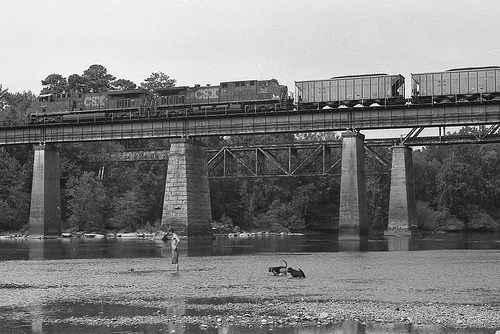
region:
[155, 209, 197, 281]
Boy standing by the river.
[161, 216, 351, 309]
A boy and his two dogs.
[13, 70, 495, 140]
Train on the tracks.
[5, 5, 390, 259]
Train crossing the river.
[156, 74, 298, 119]
CSX written on the train car.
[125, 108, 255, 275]
Pillar holding up the bridge.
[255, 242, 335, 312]
Two dogs resting for a minute.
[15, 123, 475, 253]
Four pillars are required to hold up the tracks.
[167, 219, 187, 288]
Young boy in just shorts.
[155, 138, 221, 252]
A stone pillar in the water.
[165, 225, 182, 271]
young man in water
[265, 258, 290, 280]
a dog in water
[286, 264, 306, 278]
a dog in water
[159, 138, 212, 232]
a large stone pillar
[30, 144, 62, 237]
a large stone pillar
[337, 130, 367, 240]
a large stone pillar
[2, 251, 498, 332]
debris in water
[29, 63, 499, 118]
a train on the track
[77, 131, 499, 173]
bridge for a trian in the distance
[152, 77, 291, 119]
a metal train engine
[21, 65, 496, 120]
a long train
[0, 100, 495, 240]
the trestle the train is on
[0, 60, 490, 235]
the train on the trestle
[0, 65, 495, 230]
the landscape in the background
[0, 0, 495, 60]
the sky above the train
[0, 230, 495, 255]
the water under the trestle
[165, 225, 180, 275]
a person standing under the trestle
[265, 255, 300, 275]
two dogs to the right of the person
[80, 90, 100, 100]
letters on the train on the left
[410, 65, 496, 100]
the last railroad car on the right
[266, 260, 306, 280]
Two dogs in the water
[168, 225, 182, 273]
A man standing in the water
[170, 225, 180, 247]
A shirtless person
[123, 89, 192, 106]
Two hitched freight trains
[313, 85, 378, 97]
A freight car on the bridge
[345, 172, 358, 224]
Pillar supporting the bridge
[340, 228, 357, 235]
Water mark on the pillar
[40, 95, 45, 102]
Train driver in the window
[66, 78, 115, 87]
Trees above the train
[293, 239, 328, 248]
River under the bridge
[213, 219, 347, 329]
These are two dogs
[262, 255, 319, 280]
The dogs are black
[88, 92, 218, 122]
This is a train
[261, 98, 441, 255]
These are brick poles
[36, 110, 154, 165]
This is a bridge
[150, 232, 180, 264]
This is a man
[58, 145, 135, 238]
This is a bush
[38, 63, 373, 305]
The photo is black and white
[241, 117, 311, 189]
This is another bridge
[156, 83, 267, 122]
This is a csx train